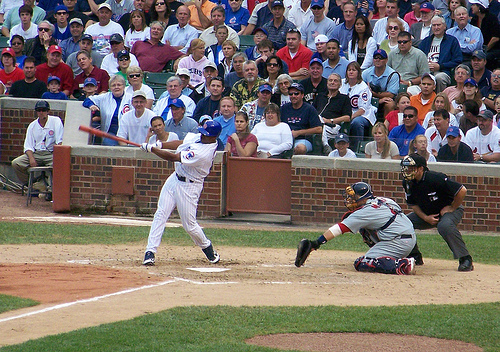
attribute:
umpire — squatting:
[391, 146, 479, 274]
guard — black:
[350, 252, 412, 274]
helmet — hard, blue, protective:
[198, 118, 224, 138]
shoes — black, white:
[135, 235, 225, 277]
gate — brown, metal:
[223, 152, 294, 220]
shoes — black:
[126, 245, 230, 275]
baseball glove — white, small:
[152, 139, 162, 149]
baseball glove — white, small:
[139, 138, 154, 153]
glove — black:
[294, 237, 314, 270]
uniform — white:
[148, 131, 245, 258]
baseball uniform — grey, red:
[326, 194, 423, 259]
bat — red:
[78, 120, 152, 155]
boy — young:
[328, 131, 356, 156]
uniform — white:
[145, 131, 213, 255]